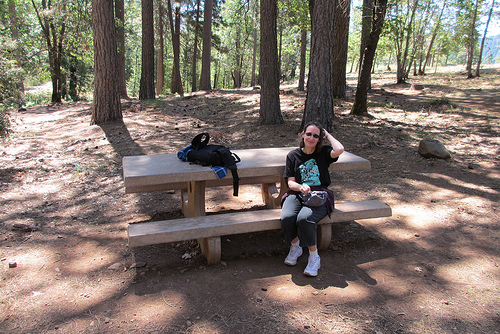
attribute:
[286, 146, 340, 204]
shirt — black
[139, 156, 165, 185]
table — wooden, wood, brown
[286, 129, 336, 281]
woman — sitting, happy, smiling, white, relaxing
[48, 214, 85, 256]
ground — dirty, sunny, dark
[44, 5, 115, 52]
trees — close, round, green, tall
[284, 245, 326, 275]
shoes — white